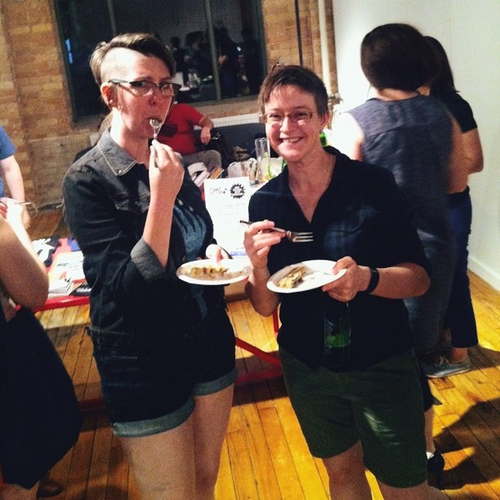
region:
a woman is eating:
[70, 29, 235, 498]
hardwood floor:
[232, 387, 291, 499]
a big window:
[74, 0, 265, 121]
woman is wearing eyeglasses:
[109, 75, 184, 97]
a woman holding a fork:
[233, 218, 323, 245]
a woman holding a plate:
[175, 242, 257, 288]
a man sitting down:
[160, 86, 230, 174]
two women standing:
[362, 19, 490, 378]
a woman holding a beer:
[313, 260, 356, 373]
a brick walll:
[2, 0, 68, 152]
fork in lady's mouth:
[145, 113, 162, 145]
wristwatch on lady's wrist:
[362, 267, 384, 297]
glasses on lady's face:
[97, 76, 187, 101]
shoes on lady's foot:
[427, 353, 474, 378]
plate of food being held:
[172, 255, 252, 287]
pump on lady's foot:
[420, 452, 447, 492]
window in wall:
[48, 2, 273, 122]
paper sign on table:
[196, 171, 259, 258]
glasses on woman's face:
[256, 106, 318, 127]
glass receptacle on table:
[251, 134, 281, 185]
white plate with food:
[274, 228, 343, 302]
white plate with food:
[185, 250, 242, 298]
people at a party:
[33, 13, 480, 493]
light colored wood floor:
[255, 446, 298, 497]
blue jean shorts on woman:
[98, 309, 246, 449]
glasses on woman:
[115, 71, 182, 110]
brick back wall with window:
[23, 38, 59, 115]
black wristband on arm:
[359, 262, 379, 299]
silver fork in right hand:
[241, 219, 310, 249]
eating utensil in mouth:
[146, 116, 173, 150]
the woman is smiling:
[238, 66, 466, 497]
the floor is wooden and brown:
[243, 416, 289, 488]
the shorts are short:
[89, 348, 241, 476]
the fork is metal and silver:
[223, 202, 318, 252]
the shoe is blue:
[424, 346, 483, 381]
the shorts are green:
[281, 353, 436, 483]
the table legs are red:
[243, 335, 278, 391]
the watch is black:
[363, 265, 391, 301]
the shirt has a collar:
[100, 131, 139, 196]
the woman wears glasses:
[104, 74, 181, 99]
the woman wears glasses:
[253, 105, 322, 127]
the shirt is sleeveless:
[352, 99, 464, 171]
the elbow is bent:
[4, 264, 61, 309]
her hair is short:
[360, 26, 442, 92]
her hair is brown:
[355, 25, 437, 87]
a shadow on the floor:
[469, 403, 486, 475]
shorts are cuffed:
[106, 404, 218, 438]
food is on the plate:
[268, 258, 349, 303]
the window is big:
[36, 1, 309, 31]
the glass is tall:
[246, 135, 273, 172]